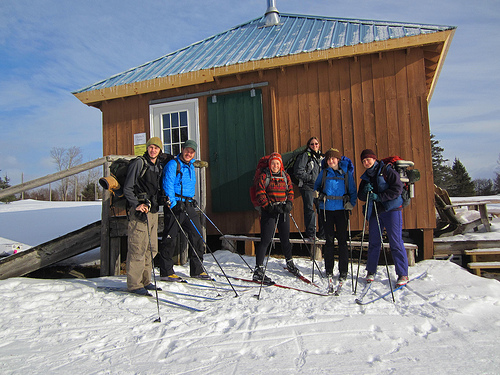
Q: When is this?
A: Daytime.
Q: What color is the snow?
A: White.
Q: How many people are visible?
A: Six.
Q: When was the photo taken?
A: Daytime.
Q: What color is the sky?
A: Blue.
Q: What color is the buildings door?
A: White.